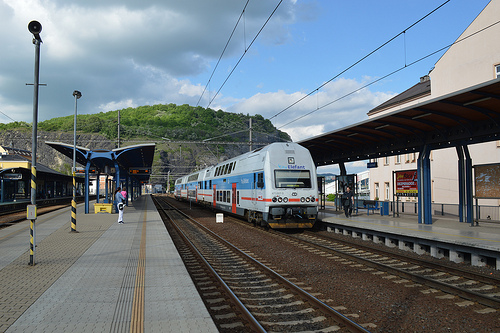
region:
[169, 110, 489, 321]
train partially in outdoor station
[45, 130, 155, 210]
curved roofs on blue supports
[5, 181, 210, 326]
bands and lines down platform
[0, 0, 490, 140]
grey clouds under blue skies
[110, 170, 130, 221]
people standing on platform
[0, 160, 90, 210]
dark train on side track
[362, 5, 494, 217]
tan building with slanted roof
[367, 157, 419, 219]
yellow windows behind elevated sign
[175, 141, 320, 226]
gray train with blue and red stripes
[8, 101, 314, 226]
mountain topped with trees in background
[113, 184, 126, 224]
woman standing on the platform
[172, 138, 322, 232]
train on train tracks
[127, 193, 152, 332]
yellow line across to the platform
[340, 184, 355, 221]
person walking on the platform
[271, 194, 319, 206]
headlights of the train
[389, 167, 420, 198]
advertisement on wall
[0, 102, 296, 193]
mountain in the distance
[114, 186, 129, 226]
woman wearing white pants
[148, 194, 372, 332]
train tracks next to platform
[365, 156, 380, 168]
sign hanging from chain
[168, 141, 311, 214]
train coming into train station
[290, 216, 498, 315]
train tracks train is on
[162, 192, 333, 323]
train tracks not being used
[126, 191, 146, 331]
yellow line painted on platform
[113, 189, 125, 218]
person standing on platform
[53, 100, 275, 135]
grass covered mountain behind train station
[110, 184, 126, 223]
person wearing pink waiting on train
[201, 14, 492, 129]
four wire lines above train tracks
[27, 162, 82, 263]
yellow stripes on two poles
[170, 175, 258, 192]
blue stripe down side of train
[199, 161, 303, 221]
blue and gray train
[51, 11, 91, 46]
white clouds in blue sky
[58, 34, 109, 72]
white clouds in blue sky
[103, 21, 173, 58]
white clouds in blue sky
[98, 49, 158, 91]
white clouds in blue sky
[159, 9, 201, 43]
white clouds in blue sky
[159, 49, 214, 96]
white clouds in blue sky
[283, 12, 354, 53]
white clouds in blue sky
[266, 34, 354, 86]
white clouds in blue sky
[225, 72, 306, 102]
white clouds in blue sky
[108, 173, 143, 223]
a mother carrying a baby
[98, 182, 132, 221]
a mother carrying a baby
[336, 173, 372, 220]
a man at the platform